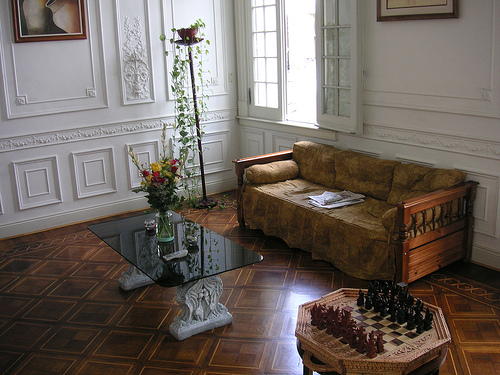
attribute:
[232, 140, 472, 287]
couch — fabric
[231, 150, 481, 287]
couch frame — wood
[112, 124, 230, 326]
flowers — colorful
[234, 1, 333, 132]
window — open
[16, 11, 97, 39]
frame — brown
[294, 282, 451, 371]
chess set — wooden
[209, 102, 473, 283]
sofa — brown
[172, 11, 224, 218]
plant — elevated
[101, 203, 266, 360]
coffee table — glasstop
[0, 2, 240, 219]
wall — white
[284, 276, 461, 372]
chess — table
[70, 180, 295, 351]
table — nice, black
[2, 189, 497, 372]
floor — wooden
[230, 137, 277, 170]
arm rest — brown, wooden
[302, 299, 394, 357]
chess pieces — black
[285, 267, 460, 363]
chess — octagon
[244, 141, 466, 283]
upholstery — brown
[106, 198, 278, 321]
table — glass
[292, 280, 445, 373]
table — brown, white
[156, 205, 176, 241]
vase — glass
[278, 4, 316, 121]
window — open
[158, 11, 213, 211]
vines — long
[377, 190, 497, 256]
arm rest — brown, wooden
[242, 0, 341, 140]
window — glass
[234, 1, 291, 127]
shutter — white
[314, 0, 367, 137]
shutter — white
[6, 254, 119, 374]
tiles — brown, floor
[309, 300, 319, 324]
chess — brown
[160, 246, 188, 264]
remote — grey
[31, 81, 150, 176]
walls — white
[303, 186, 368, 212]
paper — white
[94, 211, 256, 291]
glass — dark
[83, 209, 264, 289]
top — glass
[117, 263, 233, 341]
base — stone